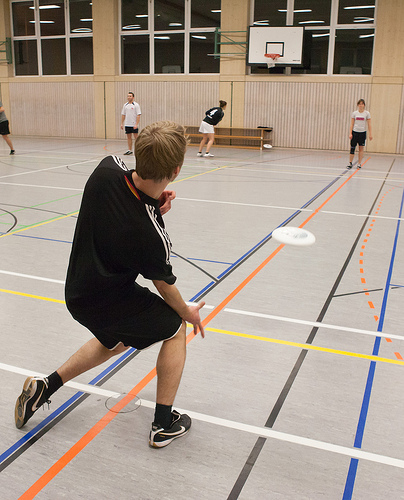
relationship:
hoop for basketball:
[263, 50, 279, 67] [249, 24, 311, 77]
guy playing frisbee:
[18, 120, 192, 443] [273, 224, 317, 247]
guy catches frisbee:
[18, 120, 192, 443] [273, 224, 317, 247]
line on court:
[188, 156, 379, 343] [1, 135, 398, 492]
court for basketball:
[1, 135, 398, 492] [249, 24, 311, 77]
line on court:
[248, 157, 391, 459] [1, 135, 398, 492]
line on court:
[331, 192, 402, 477] [1, 135, 398, 492]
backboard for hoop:
[247, 22, 305, 71] [263, 50, 279, 67]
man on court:
[118, 92, 143, 156] [1, 135, 398, 492]